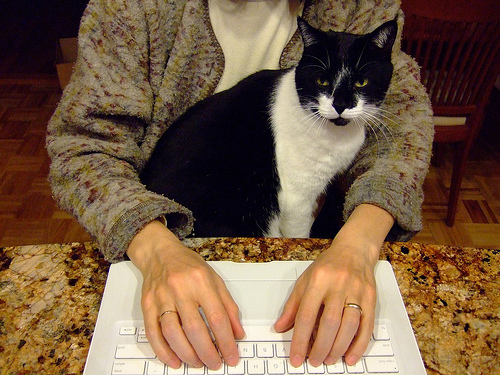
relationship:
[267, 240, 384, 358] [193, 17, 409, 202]
hand holding cat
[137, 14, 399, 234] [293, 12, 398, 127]
cat on head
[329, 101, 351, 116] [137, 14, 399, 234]
nose on cat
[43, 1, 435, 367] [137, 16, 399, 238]
person holding cat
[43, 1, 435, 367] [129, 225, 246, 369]
person has hand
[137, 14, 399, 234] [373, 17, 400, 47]
cat has ear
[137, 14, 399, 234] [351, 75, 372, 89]
cat has eye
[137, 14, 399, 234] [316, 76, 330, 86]
cat has eyes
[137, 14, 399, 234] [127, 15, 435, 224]
cat has white chest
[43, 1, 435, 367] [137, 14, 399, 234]
person holding cat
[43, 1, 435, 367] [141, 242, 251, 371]
person has hand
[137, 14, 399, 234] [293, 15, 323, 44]
cat has ear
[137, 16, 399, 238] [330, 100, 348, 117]
cat has nose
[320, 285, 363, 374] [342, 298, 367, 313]
finger has ring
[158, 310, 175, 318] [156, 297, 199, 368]
ring on finger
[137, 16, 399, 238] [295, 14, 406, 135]
cat has face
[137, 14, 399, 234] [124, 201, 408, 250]
cat sitting in lap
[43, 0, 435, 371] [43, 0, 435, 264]
person wearing housecoat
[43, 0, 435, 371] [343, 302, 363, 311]
person wears a ring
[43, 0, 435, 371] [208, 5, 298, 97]
person wears a white shirt